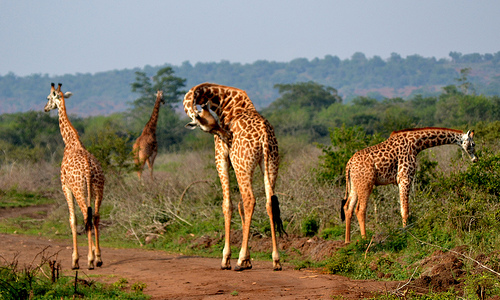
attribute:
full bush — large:
[88, 122, 145, 193]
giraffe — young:
[44, 80, 105, 270]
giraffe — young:
[343, 126, 478, 241]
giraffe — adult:
[133, 91, 164, 173]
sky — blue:
[4, 3, 484, 87]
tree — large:
[132, 62, 184, 117]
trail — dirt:
[6, 196, 387, 298]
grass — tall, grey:
[5, 135, 385, 245]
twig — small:
[45, 255, 66, 282]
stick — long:
[411, 231, 484, 275]